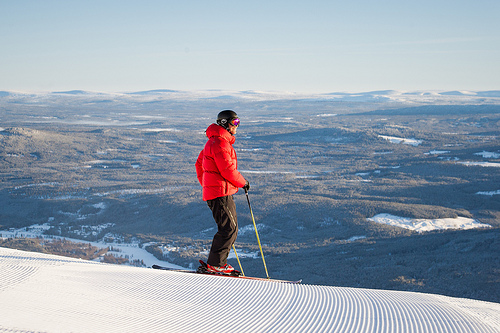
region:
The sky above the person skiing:
[0, 0, 499, 90]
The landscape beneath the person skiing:
[2, 87, 499, 301]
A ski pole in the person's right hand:
[242, 183, 269, 279]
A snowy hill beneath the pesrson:
[1, 247, 498, 332]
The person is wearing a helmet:
[217, 109, 237, 119]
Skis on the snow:
[151, 264, 301, 281]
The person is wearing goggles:
[230, 118, 240, 124]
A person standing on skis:
[153, 109, 302, 284]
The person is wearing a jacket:
[193, 126, 245, 199]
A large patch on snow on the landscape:
[368, 213, 482, 231]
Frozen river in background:
[4, 223, 195, 271]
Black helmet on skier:
[215, 108, 237, 122]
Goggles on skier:
[228, 116, 239, 126]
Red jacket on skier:
[196, 123, 246, 202]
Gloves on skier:
[241, 181, 253, 193]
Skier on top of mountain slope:
[153, 108, 305, 285]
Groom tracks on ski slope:
[5, 241, 494, 331]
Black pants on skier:
[202, 196, 239, 265]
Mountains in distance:
[8, 88, 490, 160]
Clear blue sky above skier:
[0, 1, 499, 89]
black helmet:
[214, 103, 249, 125]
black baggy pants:
[208, 194, 243, 274]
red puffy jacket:
[184, 119, 251, 194]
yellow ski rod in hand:
[239, 182, 274, 282]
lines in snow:
[209, 287, 281, 331]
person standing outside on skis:
[181, 96, 284, 296]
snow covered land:
[345, 185, 498, 276]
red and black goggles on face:
[224, 118, 246, 137]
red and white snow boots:
[205, 262, 242, 279]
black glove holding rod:
[242, 181, 254, 199]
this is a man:
[183, 170, 232, 200]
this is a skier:
[203, 172, 213, 184]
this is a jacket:
[197, 141, 216, 161]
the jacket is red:
[192, 137, 252, 208]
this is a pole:
[240, 207, 258, 274]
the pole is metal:
[232, 223, 296, 259]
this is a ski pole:
[212, 167, 344, 278]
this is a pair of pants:
[180, 197, 242, 259]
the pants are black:
[192, 202, 257, 254]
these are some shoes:
[170, 248, 247, 280]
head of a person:
[212, 98, 249, 128]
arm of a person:
[206, 145, 248, 177]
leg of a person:
[208, 190, 257, 260]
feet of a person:
[205, 253, 243, 278]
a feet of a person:
[181, 245, 260, 296]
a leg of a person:
[197, 204, 263, 250]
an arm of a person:
[190, 146, 253, 197]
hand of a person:
[232, 163, 269, 201]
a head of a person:
[211, 94, 244, 128]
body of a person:
[176, 133, 251, 228]